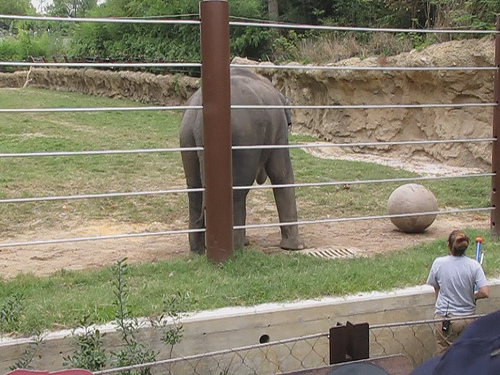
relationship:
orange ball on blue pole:
[471, 234, 486, 249] [471, 241, 483, 268]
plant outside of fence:
[53, 247, 198, 374] [0, 0, 499, 268]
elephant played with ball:
[225, 72, 289, 229] [388, 186, 438, 235]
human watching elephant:
[423, 227, 492, 359] [158, 52, 329, 254]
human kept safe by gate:
[433, 222, 490, 295] [293, 313, 424, 373]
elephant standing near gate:
[177, 64, 307, 256] [278, 350, 423, 374]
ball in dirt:
[375, 167, 458, 247] [41, 212, 131, 247]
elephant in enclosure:
[177, 64, 307, 256] [1, 2, 499, 289]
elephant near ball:
[177, 64, 307, 256] [387, 181, 438, 226]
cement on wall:
[20, 280, 491, 365] [28, 265, 489, 362]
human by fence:
[423, 227, 492, 359] [272, 22, 487, 237]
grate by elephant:
[296, 243, 363, 260] [177, 64, 307, 256]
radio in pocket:
[439, 299, 451, 335] [436, 312, 454, 333]